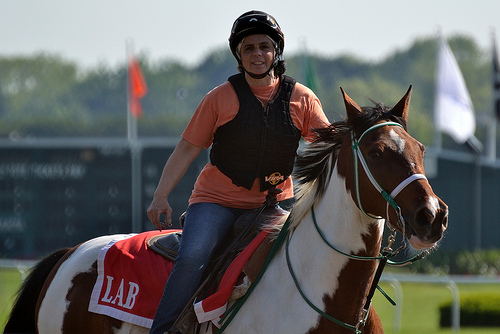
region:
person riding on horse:
[114, 11, 369, 330]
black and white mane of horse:
[286, 130, 337, 216]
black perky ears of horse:
[327, 80, 414, 116]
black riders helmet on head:
[225, 6, 282, 59]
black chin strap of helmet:
[244, 69, 272, 79]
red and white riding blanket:
[91, 234, 245, 313]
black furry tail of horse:
[9, 255, 52, 332]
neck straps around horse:
[266, 218, 383, 325]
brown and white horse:
[2, 93, 439, 324]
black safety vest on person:
[204, 71, 303, 184]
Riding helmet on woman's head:
[225, 11, 282, 76]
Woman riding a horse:
[144, 10, 336, 330]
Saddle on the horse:
[148, 187, 286, 264]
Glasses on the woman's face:
[235, 42, 269, 52]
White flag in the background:
[431, 24, 473, 145]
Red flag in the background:
[128, 61, 144, 113]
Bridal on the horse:
[343, 114, 450, 263]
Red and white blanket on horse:
[88, 227, 285, 322]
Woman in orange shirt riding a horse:
[147, 12, 339, 205]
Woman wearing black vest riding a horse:
[194, 13, 305, 208]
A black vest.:
[209, 73, 301, 191]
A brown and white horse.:
[4, 84, 451, 331]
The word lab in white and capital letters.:
[98, 272, 145, 314]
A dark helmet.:
[225, 9, 286, 79]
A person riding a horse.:
[146, 10, 336, 327]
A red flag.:
[123, 56, 148, 121]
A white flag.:
[434, 35, 479, 146]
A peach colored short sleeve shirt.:
[184, 76, 335, 208]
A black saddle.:
[148, 186, 283, 274]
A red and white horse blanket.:
[87, 209, 277, 329]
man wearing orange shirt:
[172, 46, 339, 236]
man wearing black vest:
[205, 60, 312, 204]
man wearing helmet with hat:
[214, 4, 294, 79]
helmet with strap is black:
[213, 5, 301, 86]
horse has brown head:
[320, 66, 455, 241]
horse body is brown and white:
[22, 159, 394, 326]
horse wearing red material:
[90, 208, 275, 333]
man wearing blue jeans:
[150, 183, 275, 331]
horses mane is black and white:
[246, 108, 367, 262]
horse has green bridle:
[271, 103, 448, 330]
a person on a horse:
[7, 3, 490, 325]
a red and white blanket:
[76, 241, 174, 317]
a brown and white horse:
[0, 61, 450, 328]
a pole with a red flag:
[127, 58, 145, 218]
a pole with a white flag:
[427, 8, 476, 160]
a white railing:
[388, 268, 498, 328]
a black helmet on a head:
[228, 11, 285, 71]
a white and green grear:
[335, 109, 435, 244]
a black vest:
[208, 78, 306, 191]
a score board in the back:
[9, 142, 169, 227]